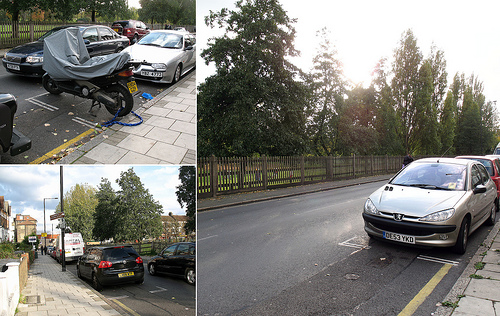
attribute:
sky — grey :
[198, 0, 498, 128]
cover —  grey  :
[42, 24, 133, 81]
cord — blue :
[108, 102, 165, 154]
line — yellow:
[399, 258, 453, 313]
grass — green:
[194, 160, 376, 196]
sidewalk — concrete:
[58, 66, 195, 163]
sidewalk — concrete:
[430, 214, 498, 312]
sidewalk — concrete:
[15, 248, 120, 313]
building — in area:
[13, 208, 38, 243]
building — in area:
[1, 192, 19, 235]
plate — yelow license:
[125, 80, 139, 94]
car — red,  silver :
[456, 155, 499, 191]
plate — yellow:
[340, 213, 437, 253]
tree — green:
[189, 2, 349, 180]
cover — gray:
[38, 30, 122, 82]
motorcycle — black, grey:
[39, 55, 141, 120]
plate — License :
[384, 230, 419, 246]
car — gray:
[356, 153, 485, 250]